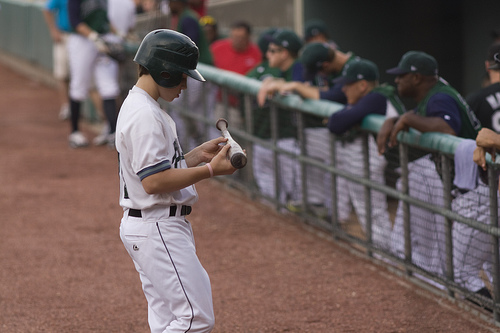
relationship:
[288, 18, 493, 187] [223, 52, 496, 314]
men leaning barrier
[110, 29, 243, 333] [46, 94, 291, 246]
boy in uniform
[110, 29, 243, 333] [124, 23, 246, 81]
boy in helmet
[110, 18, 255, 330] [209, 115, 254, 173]
boy looking at baseball bat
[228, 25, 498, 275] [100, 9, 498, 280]
teammates watching game in dugout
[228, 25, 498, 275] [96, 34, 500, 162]
teammates hanging over barrier top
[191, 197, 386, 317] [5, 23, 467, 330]
dirt on field